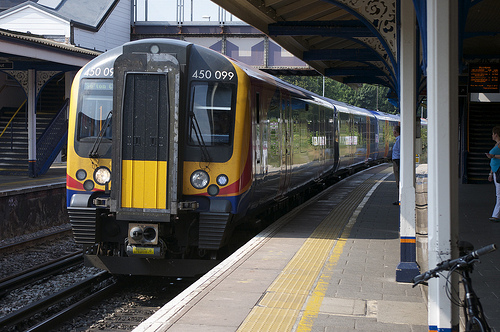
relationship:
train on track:
[65, 36, 402, 275] [1, 227, 198, 331]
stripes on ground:
[244, 164, 394, 331] [133, 164, 500, 331]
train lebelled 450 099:
[65, 36, 402, 275] [191, 67, 236, 82]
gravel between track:
[2, 256, 98, 314] [1, 227, 198, 331]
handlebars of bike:
[412, 242, 495, 286] [410, 236, 499, 330]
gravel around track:
[2, 256, 98, 314] [1, 227, 198, 331]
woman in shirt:
[484, 124, 499, 220] [484, 145, 499, 170]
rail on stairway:
[0, 99, 26, 141] [0, 70, 70, 175]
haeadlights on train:
[92, 166, 209, 189] [65, 36, 402, 275]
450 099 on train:
[191, 67, 236, 82] [65, 36, 402, 275]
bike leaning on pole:
[410, 236, 499, 330] [423, 0, 459, 330]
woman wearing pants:
[484, 124, 499, 220] [492, 172, 499, 217]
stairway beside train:
[0, 70, 70, 175] [65, 36, 402, 275]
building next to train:
[1, 0, 136, 52] [65, 36, 402, 275]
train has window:
[65, 36, 402, 275] [189, 80, 233, 144]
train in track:
[65, 36, 402, 275] [1, 227, 198, 331]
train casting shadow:
[65, 36, 402, 275] [248, 159, 398, 240]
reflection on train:
[81, 52, 121, 72] [65, 36, 402, 275]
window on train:
[189, 80, 233, 144] [65, 36, 402, 275]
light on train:
[93, 166, 112, 185] [65, 36, 402, 275]